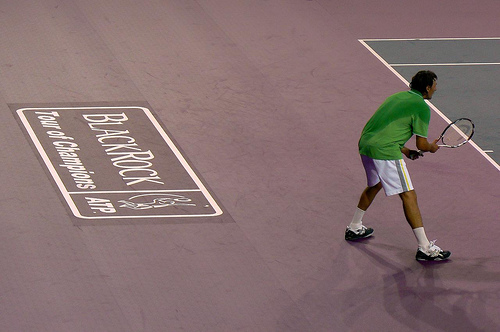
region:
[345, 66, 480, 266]
a male tennis player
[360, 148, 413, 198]
a pair of white shorts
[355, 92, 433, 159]
a green polo shirt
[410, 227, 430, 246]
a man's white sock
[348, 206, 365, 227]
a man's white sock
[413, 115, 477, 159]
a black and white tennis racket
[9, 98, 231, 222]
a tennis championship logo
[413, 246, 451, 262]
a black and white tennis shoe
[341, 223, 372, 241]
a black and white tennis shoe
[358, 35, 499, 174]
a green tennis court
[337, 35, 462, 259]
tennis player standing behind the baseline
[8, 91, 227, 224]
white logo on tennis court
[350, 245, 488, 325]
shadow of tennis player on court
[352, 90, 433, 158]
sweat soaked shirt of tennis player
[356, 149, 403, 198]
white shorts of tennis player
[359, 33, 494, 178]
white baseline on tennis court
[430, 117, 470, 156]
black and white tennis racket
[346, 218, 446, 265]
black and white shoes of tennis player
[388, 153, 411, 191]
stripe on tennis player's shorts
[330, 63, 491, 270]
tennis player wearing green shirt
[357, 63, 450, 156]
the man is sweating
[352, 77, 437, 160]
man's shirt is green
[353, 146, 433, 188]
man's shorts are white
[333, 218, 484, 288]
man's shoes are black and white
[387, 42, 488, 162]
man holding tennis racket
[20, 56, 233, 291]
white letters on tennis court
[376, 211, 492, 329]
shadow of man on court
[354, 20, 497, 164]
tennis court is green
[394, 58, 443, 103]
man's hair is black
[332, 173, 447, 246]
man's socks are white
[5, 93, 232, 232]
tennis logo on a court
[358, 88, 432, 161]
a green short sleeved shirt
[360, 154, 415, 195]
white shorts with green stripe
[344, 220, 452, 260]
a pair of black adn whtie shoes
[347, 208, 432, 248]
a pair of white socks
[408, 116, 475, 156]
a tennis racquet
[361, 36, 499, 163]
lines on a tennis court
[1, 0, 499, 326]
burgandy out of bounds area of a tennis court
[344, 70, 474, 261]
a tennis player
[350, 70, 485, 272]
A man holding a tennis racket.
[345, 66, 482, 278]
A man is playing tennis.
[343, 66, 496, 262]
The man is concentrating.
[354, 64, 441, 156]
A man wearing a green shirt.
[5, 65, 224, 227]
Blackrock logo is displayed on the ground.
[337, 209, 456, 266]
The tennis shoes look expensive.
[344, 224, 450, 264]
Black and white tennis shoes.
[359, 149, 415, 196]
Tennis shorts with grey and yellow stripes.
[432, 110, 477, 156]
Grey and white tennis racket.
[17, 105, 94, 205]
Ready to strike a tennis ball.